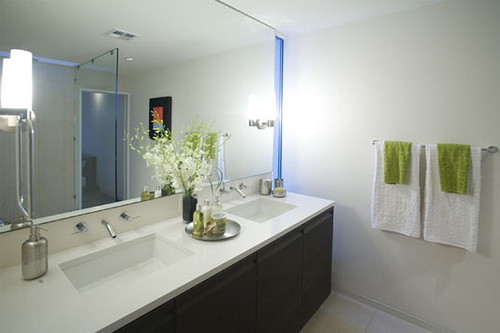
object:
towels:
[370, 137, 478, 256]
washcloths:
[368, 137, 482, 250]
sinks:
[50, 194, 298, 304]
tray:
[185, 199, 247, 246]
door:
[73, 88, 130, 212]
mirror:
[0, 14, 285, 226]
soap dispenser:
[21, 224, 50, 281]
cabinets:
[106, 204, 334, 332]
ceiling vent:
[107, 29, 136, 41]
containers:
[256, 177, 288, 198]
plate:
[184, 217, 242, 242]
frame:
[147, 94, 175, 142]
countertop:
[0, 172, 294, 332]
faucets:
[99, 216, 118, 239]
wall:
[0, 172, 273, 268]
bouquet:
[121, 120, 236, 196]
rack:
[383, 140, 477, 156]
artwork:
[148, 95, 174, 143]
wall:
[126, 38, 276, 197]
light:
[3, 36, 34, 125]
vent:
[106, 27, 141, 42]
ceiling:
[0, 0, 280, 56]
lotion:
[198, 198, 216, 217]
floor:
[299, 282, 430, 332]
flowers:
[126, 110, 229, 194]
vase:
[181, 194, 199, 221]